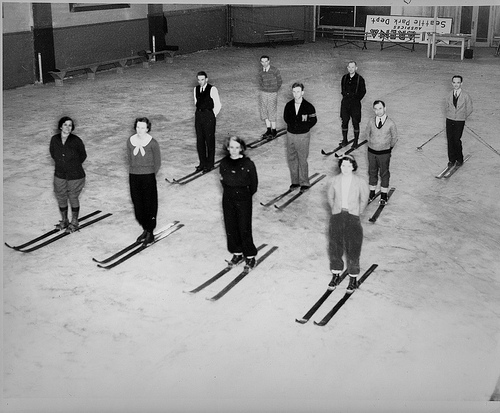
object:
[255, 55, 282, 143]
person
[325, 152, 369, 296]
person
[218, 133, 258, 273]
person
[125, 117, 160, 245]
person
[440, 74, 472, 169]
person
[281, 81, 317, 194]
person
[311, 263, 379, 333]
ski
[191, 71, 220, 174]
person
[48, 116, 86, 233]
person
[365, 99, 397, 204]
person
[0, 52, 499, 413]
snow